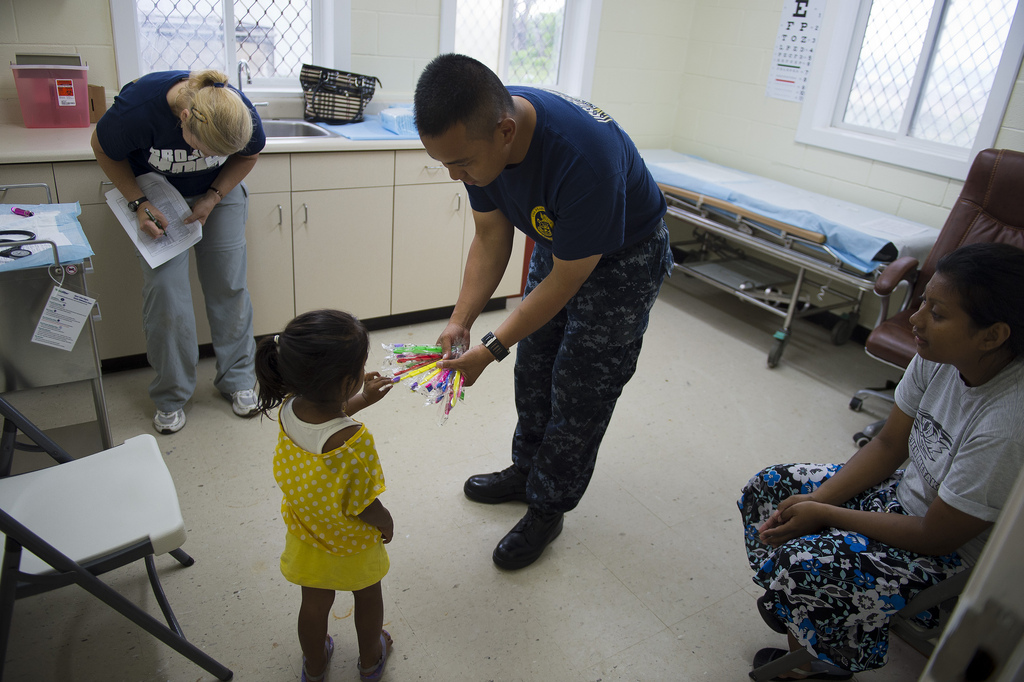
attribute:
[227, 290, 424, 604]
girl — small, brown haired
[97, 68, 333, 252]
woman — blonde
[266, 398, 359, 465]
undershirt — white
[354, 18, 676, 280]
man — black haired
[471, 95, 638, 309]
shirt — blue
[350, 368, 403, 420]
girl's hand — little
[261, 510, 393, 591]
skirt — yellow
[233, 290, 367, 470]
girl — little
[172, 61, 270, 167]
hair — blonde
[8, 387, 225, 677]
chair — dark grey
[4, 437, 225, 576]
seat — white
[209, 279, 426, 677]
child — young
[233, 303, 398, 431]
hair — black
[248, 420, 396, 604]
shirt — yellow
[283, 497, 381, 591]
skirt — yellow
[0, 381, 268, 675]
chair — empty, white